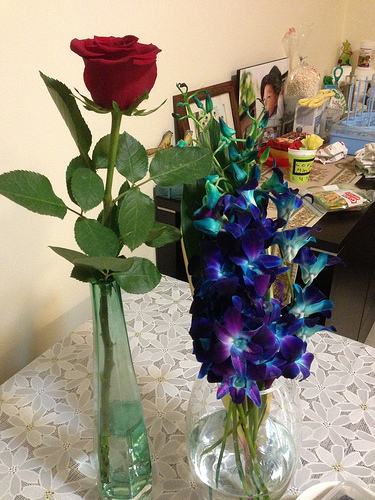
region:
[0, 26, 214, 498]
red rose with lots many leaves on it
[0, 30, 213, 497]
rose in a vase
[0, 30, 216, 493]
red rose in a glass vase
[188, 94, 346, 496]
purple and blue flowers in a vase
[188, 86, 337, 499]
flowers in a glass vase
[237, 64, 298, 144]
photo print of a child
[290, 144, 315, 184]
neon green container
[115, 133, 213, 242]
three green leaves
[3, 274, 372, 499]
vases on a white table cloth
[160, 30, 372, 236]
variety of different items on a table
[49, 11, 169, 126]
A red rose in a vase.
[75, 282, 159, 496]
The vase is clear.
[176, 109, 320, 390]
The flowers are purple.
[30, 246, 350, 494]
Two vases on a table.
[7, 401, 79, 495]
A flower pattern on the table.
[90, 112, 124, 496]
The rose has a very long stem.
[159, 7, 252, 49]
The wall is white.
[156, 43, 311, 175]
Two pictures in the background.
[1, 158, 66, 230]
A green leaf on the rose.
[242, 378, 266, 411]
A purple petal on a flower.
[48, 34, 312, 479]
flowers in the vase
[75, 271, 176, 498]
the vase is green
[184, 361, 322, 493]
the vase is transparent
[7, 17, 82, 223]
the wall is clean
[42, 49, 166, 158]
the rose is red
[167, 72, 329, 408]
the orchids are colorful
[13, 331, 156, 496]
the tablecloth is white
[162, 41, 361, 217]
the pictures are leaning on the wall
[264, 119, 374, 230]
clutters on the counter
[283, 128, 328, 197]
the cup is green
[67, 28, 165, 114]
a red rose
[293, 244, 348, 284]
a blue flower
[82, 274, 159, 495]
a long glass vase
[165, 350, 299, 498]
a wide glass vase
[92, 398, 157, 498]
water in the vase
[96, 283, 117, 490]
the stem of a rose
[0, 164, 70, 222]
the leaf of a rose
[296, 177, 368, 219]
a clear plastic bag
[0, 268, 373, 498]
a white floral tablecloth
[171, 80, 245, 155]
a brown picture frame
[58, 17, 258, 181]
the flower is red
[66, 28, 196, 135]
the flower is red